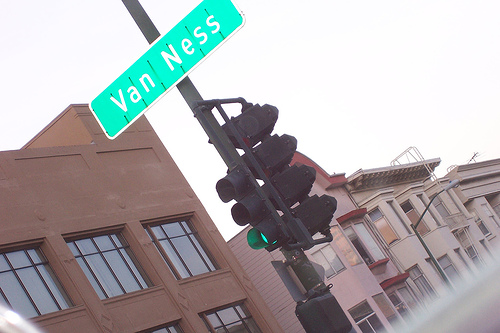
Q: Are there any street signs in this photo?
A: Yes, there is a street sign.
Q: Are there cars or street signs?
A: Yes, there is a street sign.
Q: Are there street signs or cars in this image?
A: Yes, there is a street sign.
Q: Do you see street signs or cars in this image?
A: Yes, there is a street sign.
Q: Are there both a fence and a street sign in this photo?
A: No, there is a street sign but no fences.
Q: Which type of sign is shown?
A: The sign is a street sign.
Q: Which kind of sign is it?
A: The sign is a street sign.